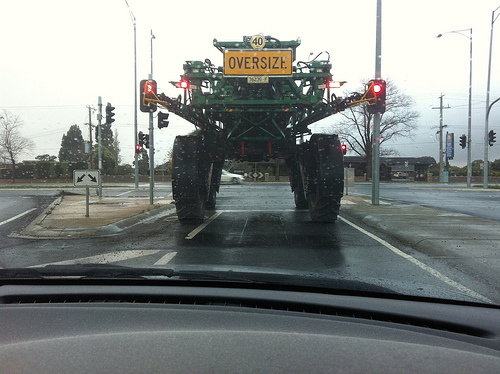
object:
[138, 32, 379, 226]
vehicle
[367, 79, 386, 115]
traffic light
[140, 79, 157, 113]
traffic light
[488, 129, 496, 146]
traffic light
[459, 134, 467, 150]
traffic light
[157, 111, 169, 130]
traffic light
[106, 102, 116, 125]
traffic light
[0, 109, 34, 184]
tree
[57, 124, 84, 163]
tree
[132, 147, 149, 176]
tree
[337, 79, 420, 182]
tree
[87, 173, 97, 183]
black arrow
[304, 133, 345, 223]
tire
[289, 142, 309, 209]
tire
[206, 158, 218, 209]
tire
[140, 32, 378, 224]
car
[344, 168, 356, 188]
sign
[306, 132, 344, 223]
rear wheel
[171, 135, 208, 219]
tire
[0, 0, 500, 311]
windshield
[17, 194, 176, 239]
median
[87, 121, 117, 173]
tree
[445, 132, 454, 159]
sign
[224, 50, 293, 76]
sign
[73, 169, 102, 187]
sign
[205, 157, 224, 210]
front wheel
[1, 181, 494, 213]
intersection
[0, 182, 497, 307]
road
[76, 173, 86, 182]
arrows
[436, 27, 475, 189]
light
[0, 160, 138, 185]
field